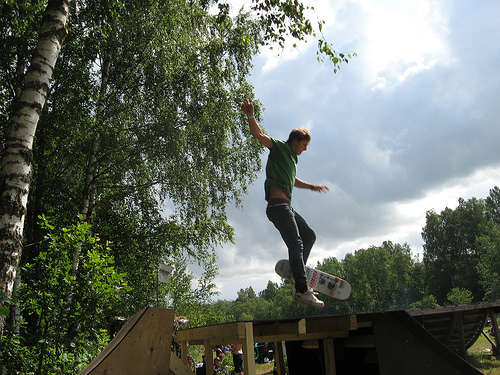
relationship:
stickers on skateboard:
[313, 270, 327, 287] [263, 246, 362, 305]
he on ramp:
[235, 97, 383, 346] [180, 289, 325, 343]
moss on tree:
[3, 110, 33, 158] [9, 86, 31, 170]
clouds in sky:
[196, 0, 499, 288] [345, 116, 428, 176]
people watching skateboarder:
[191, 343, 255, 367] [213, 120, 335, 318]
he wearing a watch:
[235, 97, 383, 346] [237, 102, 267, 122]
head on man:
[269, 105, 317, 162] [226, 94, 334, 307]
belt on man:
[264, 184, 301, 217] [233, 78, 344, 308]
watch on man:
[240, 105, 268, 124] [220, 88, 353, 299]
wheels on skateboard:
[324, 268, 350, 302] [264, 247, 358, 308]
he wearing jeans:
[235, 97, 383, 346] [255, 202, 338, 295]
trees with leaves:
[171, 189, 499, 324] [348, 250, 480, 297]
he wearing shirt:
[235, 97, 383, 346] [260, 126, 301, 197]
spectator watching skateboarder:
[190, 345, 215, 367] [236, 85, 326, 310]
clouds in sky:
[269, 38, 401, 238] [161, 0, 494, 298]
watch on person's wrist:
[240, 105, 268, 124] [241, 110, 260, 125]